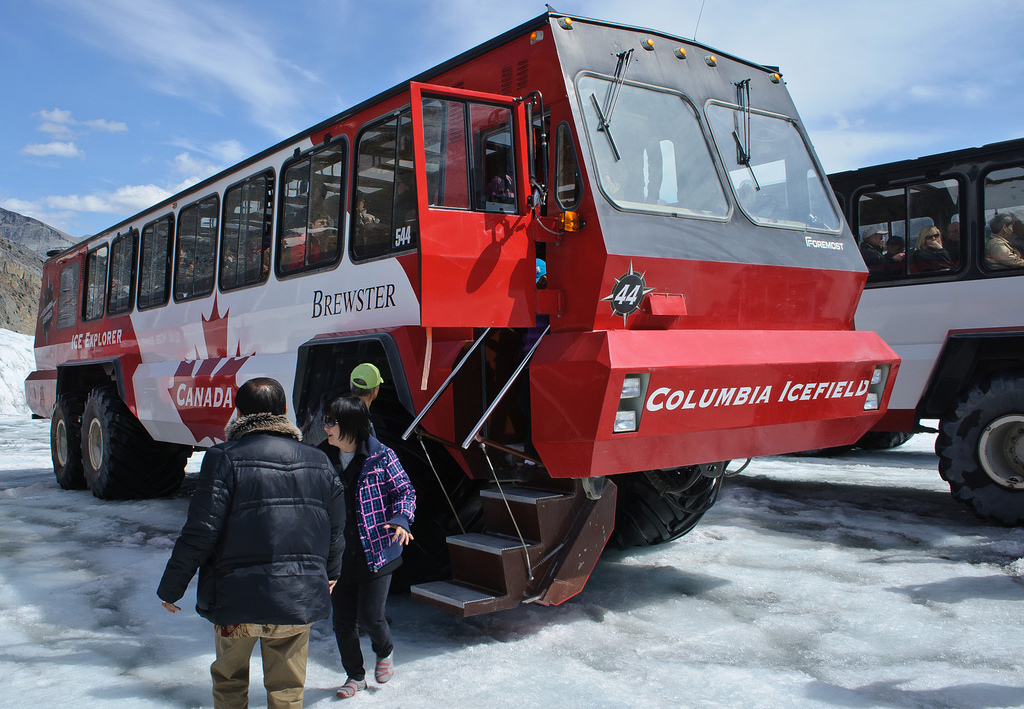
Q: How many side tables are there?
A: 2.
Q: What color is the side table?
A: Brown.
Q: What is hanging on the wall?
A: Picture frame.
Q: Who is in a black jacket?
A: The man in the back.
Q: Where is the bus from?
A: Canada.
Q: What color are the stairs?
A: Brown.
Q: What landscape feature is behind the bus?
A: A mountain.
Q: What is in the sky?
A: Clouds.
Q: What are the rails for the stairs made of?
A: Metal.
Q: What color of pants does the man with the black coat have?
A: Brown.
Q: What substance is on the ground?
A: Snow and ice.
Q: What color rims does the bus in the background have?
A: White rims.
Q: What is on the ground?
A: Snow.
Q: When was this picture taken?
A: Wintertime.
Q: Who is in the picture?
A: Two men and a woman.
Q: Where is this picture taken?
A: Canada.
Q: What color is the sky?
A: Blue.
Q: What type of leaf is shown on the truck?
A: Maple.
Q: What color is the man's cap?
A: Green.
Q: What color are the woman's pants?
A: Black.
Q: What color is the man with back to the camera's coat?
A: Black.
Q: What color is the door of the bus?
A: Red.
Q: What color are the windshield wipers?
A: Black.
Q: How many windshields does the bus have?
A: Two.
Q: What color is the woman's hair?
A: Black.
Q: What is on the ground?
A: Snow.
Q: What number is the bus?
A: 44.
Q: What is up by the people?
A: Steps.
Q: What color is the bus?
A: Red and white.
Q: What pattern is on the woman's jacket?
A: Plaid.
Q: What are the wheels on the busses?
A: Big tires.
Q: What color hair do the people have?
A: Black.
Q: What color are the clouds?
A: White.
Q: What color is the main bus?
A: White and red.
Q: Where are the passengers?
A: Inside the buses.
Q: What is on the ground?
A: Ice and snow.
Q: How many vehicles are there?
A: Two.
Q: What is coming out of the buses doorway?
A: Steps.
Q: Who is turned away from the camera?
A: Man in black jacket.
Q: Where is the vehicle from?
A: Canada.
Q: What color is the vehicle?
A: Red and white.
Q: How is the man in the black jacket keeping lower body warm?
A: Tan pants.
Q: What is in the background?
A: Rock structure.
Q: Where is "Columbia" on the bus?
A: Front bumper.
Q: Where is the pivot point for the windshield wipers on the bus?
A: Above the front windows.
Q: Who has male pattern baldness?
A: Man in black jacket.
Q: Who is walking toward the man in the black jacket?
A: Woman in blue and pink jacket.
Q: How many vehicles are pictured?
A: Two.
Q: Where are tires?
A: On the vehicles.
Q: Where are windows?
A: On the bus.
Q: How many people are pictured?
A: Three.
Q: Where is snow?
A: On the ground.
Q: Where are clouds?
A: In the sky.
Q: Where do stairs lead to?
A: Inside the bus.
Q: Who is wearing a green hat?
A: One person.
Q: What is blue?
A: Sky.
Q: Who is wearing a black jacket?
A: One man.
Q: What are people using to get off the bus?
A: Stairs.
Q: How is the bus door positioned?
A: Open.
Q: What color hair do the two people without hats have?
A: Black.